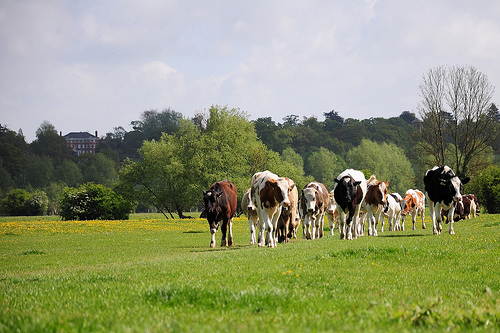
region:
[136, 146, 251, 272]
a cow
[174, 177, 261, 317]
a cow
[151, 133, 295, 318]
a cow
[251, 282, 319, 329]
the grass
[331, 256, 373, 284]
the grass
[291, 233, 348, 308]
the grass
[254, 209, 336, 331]
the grass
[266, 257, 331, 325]
the grass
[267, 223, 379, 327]
the grass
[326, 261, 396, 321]
the grass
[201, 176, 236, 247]
a dark brown cow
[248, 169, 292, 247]
a white and brown cow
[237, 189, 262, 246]
a white and brown cow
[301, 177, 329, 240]
a white and brown cow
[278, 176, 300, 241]
a white and brown cow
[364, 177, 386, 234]
a white and brown cow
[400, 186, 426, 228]
a white and brown cow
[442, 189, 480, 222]
a white and brown cow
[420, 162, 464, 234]
a black and white cow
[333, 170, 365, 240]
a black and white cow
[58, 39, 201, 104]
the sky is blue and clear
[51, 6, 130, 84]
the sky is blue and clear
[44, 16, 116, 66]
the sky is blue and clear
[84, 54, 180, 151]
the sky is blue and clear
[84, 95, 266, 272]
the sky is blue and clear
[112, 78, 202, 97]
the sky is blue and clear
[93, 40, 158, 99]
the sky is blue and clear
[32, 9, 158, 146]
the sky is blue and clear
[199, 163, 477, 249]
a herd of cows on the field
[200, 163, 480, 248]
herd of cows in a pasture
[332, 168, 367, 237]
a white and black cow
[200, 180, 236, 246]
a brown cow with white and brown legs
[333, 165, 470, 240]
two black and white cows walking in front of other cows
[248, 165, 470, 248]
three cows walking before the other cows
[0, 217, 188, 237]
wild yellow flowers on the field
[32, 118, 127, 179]
a brick building surrounded by trees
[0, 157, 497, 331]
a herd of cows walking in the pasture